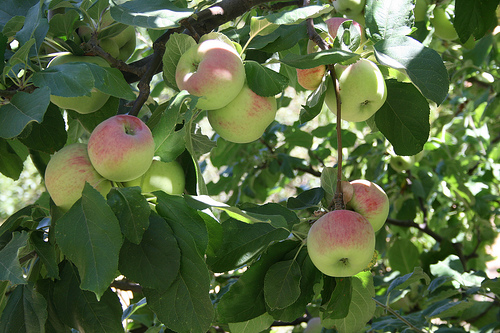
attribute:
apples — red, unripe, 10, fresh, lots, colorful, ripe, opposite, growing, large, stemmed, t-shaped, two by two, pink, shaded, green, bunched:
[189, 52, 286, 148]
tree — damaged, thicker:
[97, 18, 417, 307]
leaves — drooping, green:
[29, 57, 109, 120]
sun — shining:
[183, 159, 274, 219]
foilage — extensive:
[105, 205, 226, 295]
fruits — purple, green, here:
[158, 53, 317, 197]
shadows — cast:
[148, 153, 256, 247]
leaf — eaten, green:
[60, 231, 139, 329]